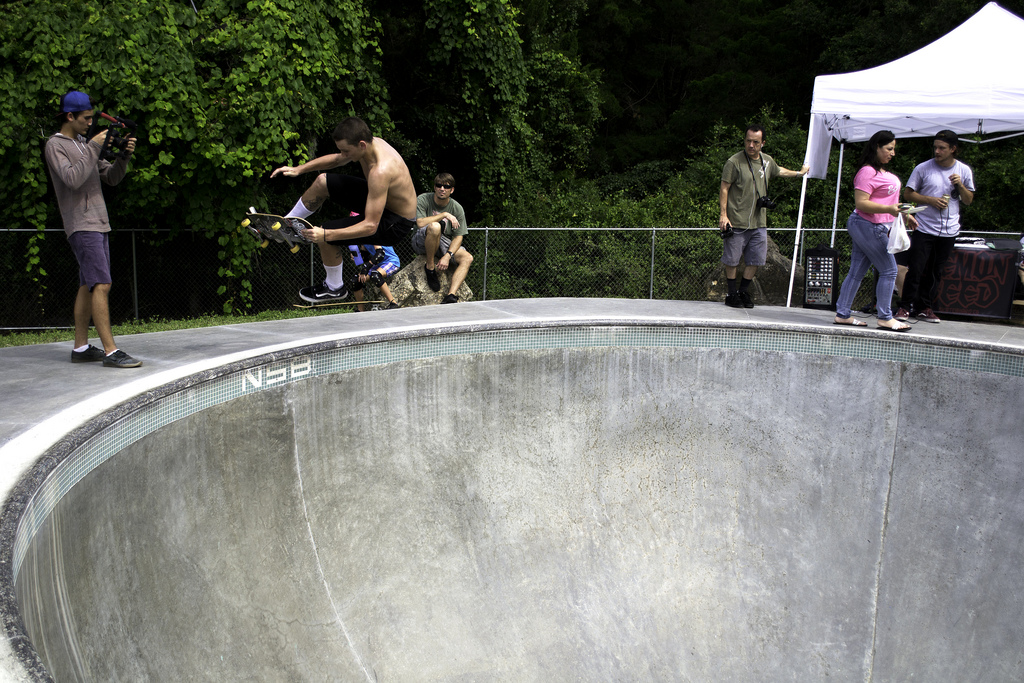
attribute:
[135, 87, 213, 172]
leaves — green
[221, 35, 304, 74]
leaves — green 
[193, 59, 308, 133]
leaves — green 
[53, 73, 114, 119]
cap — blue 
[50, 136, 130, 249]
shirt — gray 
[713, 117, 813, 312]
person — standing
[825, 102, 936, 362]
person — standing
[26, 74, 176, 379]
person — standing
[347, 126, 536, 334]
person — sitting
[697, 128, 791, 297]
person — standing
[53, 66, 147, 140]
hat — blue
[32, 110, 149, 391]
man — young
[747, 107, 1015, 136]
tent — white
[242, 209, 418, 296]
man — young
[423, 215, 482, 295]
man — young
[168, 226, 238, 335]
fence — grey